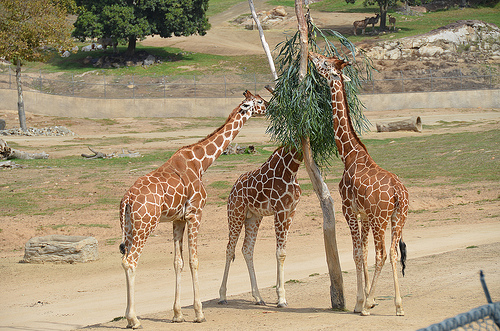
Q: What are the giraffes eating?
A: Leaves.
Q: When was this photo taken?
A: Daytime.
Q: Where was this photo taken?
A: In a zoo.